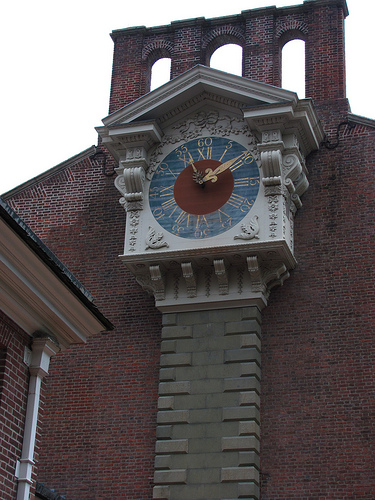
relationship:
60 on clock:
[195, 137, 213, 147] [145, 134, 263, 240]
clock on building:
[148, 137, 260, 239] [0, 8, 373, 498]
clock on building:
[137, 107, 258, 258] [0, 8, 373, 498]